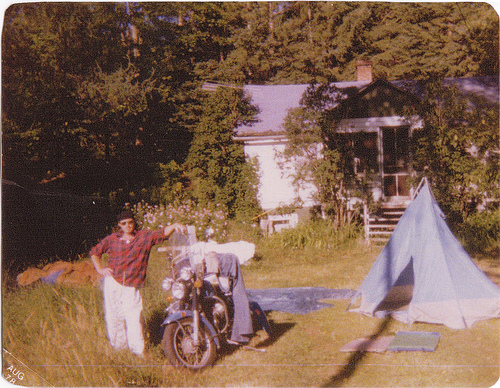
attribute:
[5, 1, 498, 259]
forest — dense 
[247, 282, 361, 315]
tarp — blue 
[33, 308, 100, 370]
weeds — tall 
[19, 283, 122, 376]
grass — tall 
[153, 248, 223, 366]
bike — parked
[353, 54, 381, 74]
chimney — brick 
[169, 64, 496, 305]
house — white 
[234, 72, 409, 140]
roof — blue 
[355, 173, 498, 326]
tent — pitched, light blue 